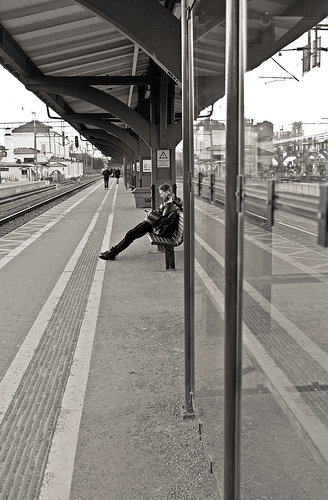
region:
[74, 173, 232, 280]
man sitting on a bench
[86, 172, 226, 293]
man in black pants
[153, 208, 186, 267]
black backpack on a bench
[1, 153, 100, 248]
rail tracks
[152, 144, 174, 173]
white sign with a triangle symbol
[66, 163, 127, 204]
people walking on a train platform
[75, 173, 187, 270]
man texting on a phone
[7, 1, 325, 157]
metal platform roof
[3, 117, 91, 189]
white building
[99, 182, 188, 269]
man on train platform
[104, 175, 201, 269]
person sitting on a bench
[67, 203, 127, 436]
white lines painted on cement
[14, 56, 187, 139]
metal arches attached to roofing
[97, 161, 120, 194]
man standing in train station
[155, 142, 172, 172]
sign posted in train station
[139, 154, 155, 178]
white sign posted on train station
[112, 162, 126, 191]
person walking in a train station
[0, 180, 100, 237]
train tracks going through train station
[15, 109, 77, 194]
buildings across the street from a gas station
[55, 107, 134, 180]
metal arhes attached to roofing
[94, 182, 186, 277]
This is a person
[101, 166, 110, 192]
This is a person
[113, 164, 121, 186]
This is a person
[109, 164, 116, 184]
This is a person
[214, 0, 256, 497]
This is a pole post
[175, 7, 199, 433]
This is a pole post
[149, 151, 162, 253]
This is a pole post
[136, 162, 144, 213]
This is a pole post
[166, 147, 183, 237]
This is a pole post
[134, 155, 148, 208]
This is a pole post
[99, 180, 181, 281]
woman seated at railway station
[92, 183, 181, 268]
This is a woman seated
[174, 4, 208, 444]
This is a pillar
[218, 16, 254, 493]
This is a pillar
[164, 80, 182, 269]
This is a pillar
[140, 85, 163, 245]
This is a pillar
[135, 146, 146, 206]
This is a pillar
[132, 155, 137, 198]
This is a pillar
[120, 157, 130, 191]
This is a pillar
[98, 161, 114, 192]
This is a person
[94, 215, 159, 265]
legs are stretched out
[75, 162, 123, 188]
people walking alongside the tracks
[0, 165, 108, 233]
two parallel sets of train tracks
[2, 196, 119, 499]
two parallel lines painted on the ground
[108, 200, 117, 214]
paint is fading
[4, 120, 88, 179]
white building with a dark roof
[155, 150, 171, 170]
sign on the pole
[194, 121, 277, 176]
reflection in the glass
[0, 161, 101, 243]
no trains on the tracks